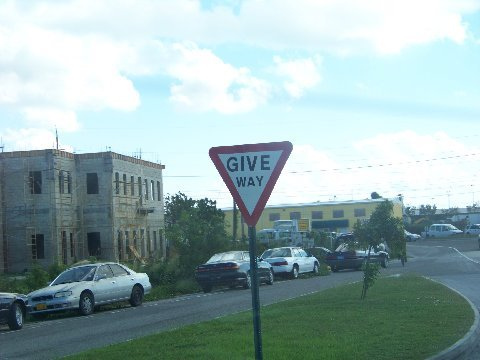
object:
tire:
[79, 290, 96, 315]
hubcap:
[84, 297, 93, 312]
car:
[194, 251, 274, 293]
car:
[260, 245, 321, 279]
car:
[327, 238, 389, 272]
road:
[0, 237, 478, 358]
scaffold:
[0, 150, 154, 273]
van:
[428, 222, 463, 238]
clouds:
[0, 0, 479, 207]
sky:
[45, 29, 165, 97]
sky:
[378, 69, 435, 114]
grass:
[89, 272, 476, 357]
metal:
[125, 189, 159, 257]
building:
[0, 125, 166, 271]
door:
[241, 251, 261, 276]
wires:
[380, 158, 441, 167]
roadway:
[432, 230, 479, 360]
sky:
[313, 64, 347, 123]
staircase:
[130, 243, 150, 266]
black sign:
[208, 139, 292, 226]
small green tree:
[361, 259, 380, 300]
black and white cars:
[194, 246, 320, 293]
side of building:
[216, 194, 401, 252]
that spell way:
[236, 175, 263, 188]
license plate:
[35, 304, 47, 310]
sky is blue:
[388, 59, 468, 110]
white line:
[449, 248, 480, 264]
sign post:
[248, 221, 263, 360]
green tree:
[344, 198, 408, 301]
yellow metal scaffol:
[121, 224, 167, 268]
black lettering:
[227, 154, 274, 187]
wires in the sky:
[420, 178, 479, 197]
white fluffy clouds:
[58, 24, 266, 115]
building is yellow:
[219, 197, 402, 247]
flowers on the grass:
[395, 285, 447, 316]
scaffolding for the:
[133, 204, 156, 218]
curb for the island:
[215, 317, 420, 349]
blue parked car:
[27, 260, 151, 317]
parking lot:
[0, 212, 480, 359]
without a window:
[84, 172, 99, 193]